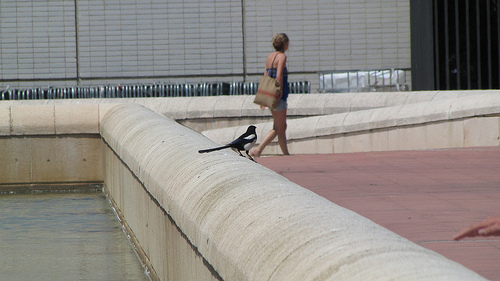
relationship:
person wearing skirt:
[248, 32, 296, 156] [270, 97, 288, 114]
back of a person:
[266, 42, 285, 73] [258, 10, 296, 150]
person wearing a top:
[255, 24, 303, 159] [265, 68, 272, 78]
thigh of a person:
[273, 107, 285, 131] [263, 19, 293, 154]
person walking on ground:
[248, 32, 296, 156] [337, 154, 389, 207]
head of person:
[273, 32, 291, 49] [241, 24, 298, 154]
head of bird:
[246, 126, 257, 138] [182, 121, 262, 162]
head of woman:
[273, 28, 293, 53] [256, 22, 294, 162]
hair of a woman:
[271, 27, 282, 51] [261, 29, 300, 159]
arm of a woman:
[277, 55, 287, 86] [261, 10, 298, 166]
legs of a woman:
[266, 115, 282, 157] [253, 23, 312, 164]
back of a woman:
[266, 51, 285, 73] [252, 33, 298, 158]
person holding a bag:
[248, 32, 296, 156] [250, 74, 287, 108]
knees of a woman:
[274, 118, 287, 133] [257, 18, 296, 165]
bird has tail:
[197, 124, 262, 164] [198, 144, 228, 155]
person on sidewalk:
[248, 32, 296, 156] [245, 138, 497, 278]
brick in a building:
[195, 123, 255, 153] [0, 83, 491, 279]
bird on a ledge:
[194, 117, 268, 156] [92, 96, 497, 279]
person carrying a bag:
[248, 32, 296, 156] [250, 77, 287, 108]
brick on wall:
[78, 69, 92, 76] [0, 5, 407, 77]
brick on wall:
[105, 67, 120, 78] [4, 2, 413, 96]